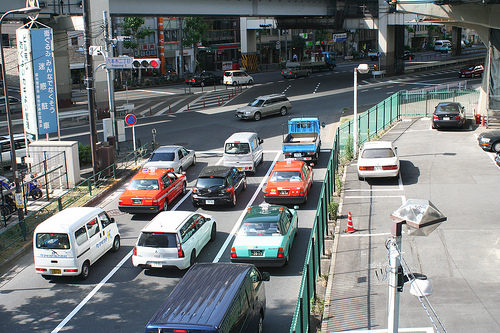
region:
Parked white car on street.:
[357, 140, 400, 182]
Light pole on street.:
[386, 197, 447, 332]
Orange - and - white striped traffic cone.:
[343, 211, 357, 233]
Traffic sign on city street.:
[124, 113, 139, 157]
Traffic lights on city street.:
[131, 58, 159, 67]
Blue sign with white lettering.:
[30, 26, 58, 134]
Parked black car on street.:
[431, 102, 466, 128]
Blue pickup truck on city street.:
[281, 116, 326, 166]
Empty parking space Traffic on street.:
[334, 194, 409, 236]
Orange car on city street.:
[117, 165, 188, 214]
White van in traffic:
[34, 205, 121, 279]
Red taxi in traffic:
[119, 166, 188, 211]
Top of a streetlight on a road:
[388, 197, 446, 332]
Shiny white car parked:
[357, 136, 401, 180]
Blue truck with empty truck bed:
[283, 116, 325, 158]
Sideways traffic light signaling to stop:
[131, 58, 161, 69]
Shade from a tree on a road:
[11, 279, 118, 331]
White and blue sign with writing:
[16, 28, 60, 133]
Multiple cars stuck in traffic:
[108, 133, 319, 269]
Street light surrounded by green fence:
[351, 60, 400, 141]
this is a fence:
[264, 69, 469, 329]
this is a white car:
[133, 209, 217, 272]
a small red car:
[110, 165, 194, 215]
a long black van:
[147, 250, 280, 332]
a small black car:
[426, 94, 471, 135]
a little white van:
[13, 203, 131, 283]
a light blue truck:
[276, 105, 331, 166]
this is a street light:
[348, 43, 374, 165]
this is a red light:
[146, 55, 165, 71]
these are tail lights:
[217, 237, 289, 262]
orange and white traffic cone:
[345, 210, 357, 232]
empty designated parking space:
[342, 188, 412, 235]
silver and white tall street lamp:
[350, 60, 369, 153]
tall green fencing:
[340, 98, 399, 141]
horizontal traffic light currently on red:
[108, 56, 162, 71]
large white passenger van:
[30, 200, 122, 279]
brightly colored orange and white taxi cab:
[122, 165, 190, 212]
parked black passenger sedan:
[426, 101, 471, 130]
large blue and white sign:
[12, 23, 58, 144]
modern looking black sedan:
[187, 165, 249, 208]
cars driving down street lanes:
[42, 117, 325, 286]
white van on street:
[28, 199, 123, 276]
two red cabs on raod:
[119, 158, 309, 208]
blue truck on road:
[275, 113, 317, 157]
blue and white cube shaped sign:
[25, 26, 64, 135]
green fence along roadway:
[293, 80, 469, 313]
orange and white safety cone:
[345, 201, 357, 234]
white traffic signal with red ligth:
[109, 53, 162, 73]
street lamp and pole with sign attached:
[3, 4, 60, 249]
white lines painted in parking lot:
[332, 163, 412, 248]